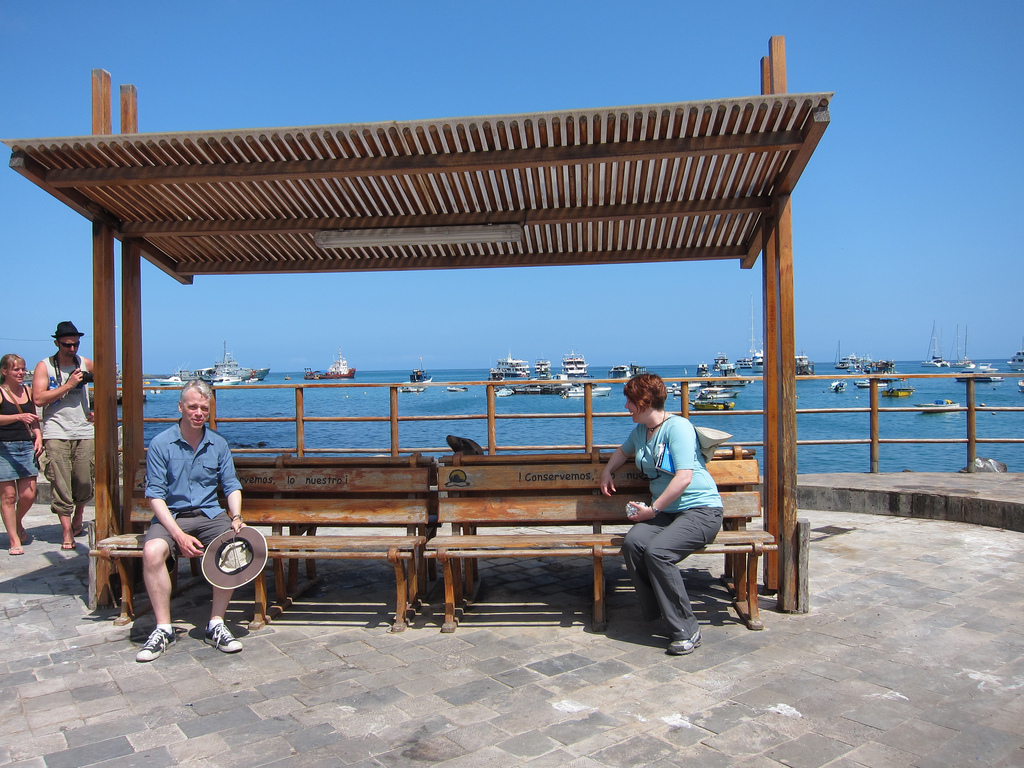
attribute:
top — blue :
[614, 417, 723, 517]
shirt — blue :
[148, 426, 244, 528]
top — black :
[3, 395, 34, 443]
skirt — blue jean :
[5, 443, 57, 483]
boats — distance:
[202, 331, 894, 409]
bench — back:
[113, 439, 785, 614]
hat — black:
[39, 318, 89, 355]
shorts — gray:
[150, 512, 233, 547]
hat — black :
[53, 322, 82, 344]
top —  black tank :
[7, 389, 36, 450]